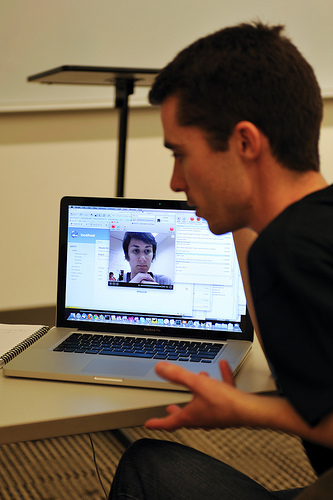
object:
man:
[109, 21, 332, 500]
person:
[122, 232, 157, 283]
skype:
[68, 227, 110, 244]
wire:
[88, 436, 108, 499]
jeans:
[111, 435, 272, 500]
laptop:
[3, 196, 254, 392]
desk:
[0, 322, 279, 445]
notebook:
[0, 323, 51, 367]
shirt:
[247, 182, 333, 427]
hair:
[147, 24, 323, 174]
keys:
[98, 349, 154, 358]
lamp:
[27, 64, 158, 199]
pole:
[116, 105, 128, 196]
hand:
[145, 361, 234, 431]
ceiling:
[0, 0, 330, 57]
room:
[0, 0, 332, 491]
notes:
[2, 324, 16, 336]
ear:
[236, 121, 261, 159]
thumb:
[156, 362, 197, 389]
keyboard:
[53, 333, 225, 364]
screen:
[64, 204, 247, 321]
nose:
[170, 152, 185, 192]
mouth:
[187, 202, 199, 216]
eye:
[173, 154, 184, 162]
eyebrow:
[166, 141, 176, 148]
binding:
[1, 325, 48, 366]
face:
[128, 238, 153, 271]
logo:
[144, 328, 160, 332]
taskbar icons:
[71, 313, 75, 317]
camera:
[157, 204, 158, 206]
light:
[158, 202, 160, 204]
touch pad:
[81, 355, 157, 376]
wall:
[0, 0, 174, 63]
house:
[0, 0, 333, 499]